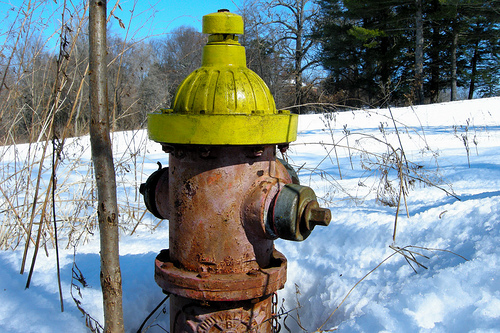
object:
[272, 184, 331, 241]
arm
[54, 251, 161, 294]
shadow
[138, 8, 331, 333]
fire hydrant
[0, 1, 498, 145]
woods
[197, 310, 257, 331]
word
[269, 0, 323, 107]
tree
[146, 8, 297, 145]
top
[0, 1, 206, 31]
sky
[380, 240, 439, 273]
branch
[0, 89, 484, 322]
snow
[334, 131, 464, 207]
branch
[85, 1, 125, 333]
tree